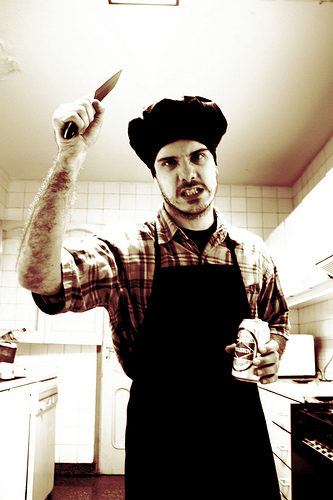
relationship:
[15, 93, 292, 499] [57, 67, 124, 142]
man holding knife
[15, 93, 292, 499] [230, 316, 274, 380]
man holding can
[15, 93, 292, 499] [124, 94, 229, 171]
man wearing chef hat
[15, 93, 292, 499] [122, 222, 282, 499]
man wearing apron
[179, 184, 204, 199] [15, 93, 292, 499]
mouth of man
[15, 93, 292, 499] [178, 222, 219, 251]
man wearing t-shirt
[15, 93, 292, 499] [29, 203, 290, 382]
man wearing shirt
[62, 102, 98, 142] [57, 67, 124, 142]
handle of knife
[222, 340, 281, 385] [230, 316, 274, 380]
hand holding soda can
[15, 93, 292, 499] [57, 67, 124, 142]
man wielding knife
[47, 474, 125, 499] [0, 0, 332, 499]
floor in kitchen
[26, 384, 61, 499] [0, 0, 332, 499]
dishwasher in kitchen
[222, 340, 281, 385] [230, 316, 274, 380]
hand holding can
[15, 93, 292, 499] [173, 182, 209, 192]
man has mustache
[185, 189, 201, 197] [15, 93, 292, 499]
teeth of man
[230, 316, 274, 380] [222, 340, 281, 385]
can in hand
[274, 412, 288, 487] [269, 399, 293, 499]
handles on drawers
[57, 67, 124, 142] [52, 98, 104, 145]
knife in hand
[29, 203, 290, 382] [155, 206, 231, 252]
shirt has collar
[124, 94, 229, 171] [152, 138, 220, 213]
chef hat on head